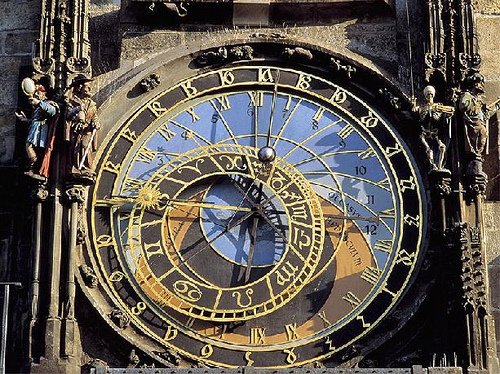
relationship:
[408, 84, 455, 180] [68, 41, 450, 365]
statue on right side of clock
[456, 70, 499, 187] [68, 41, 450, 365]
statue on right side of clock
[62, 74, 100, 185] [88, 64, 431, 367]
sculpture on left side of clock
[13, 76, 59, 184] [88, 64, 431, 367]
sculpture on left side of clock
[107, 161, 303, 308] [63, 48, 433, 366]
hands of astronomical clock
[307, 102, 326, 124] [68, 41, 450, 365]
roman numeral on clock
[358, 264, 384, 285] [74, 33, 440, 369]
numeral on astrological clock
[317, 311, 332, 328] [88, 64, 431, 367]
x on clock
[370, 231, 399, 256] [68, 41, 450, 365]
numeral on clock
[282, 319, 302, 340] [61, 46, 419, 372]
numeral on clock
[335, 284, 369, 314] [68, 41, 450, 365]
xi on clock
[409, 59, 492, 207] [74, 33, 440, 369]
skeleton on astrological clock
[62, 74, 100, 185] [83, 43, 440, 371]
sculpture by astrological clock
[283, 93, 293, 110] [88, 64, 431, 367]
number i on clock